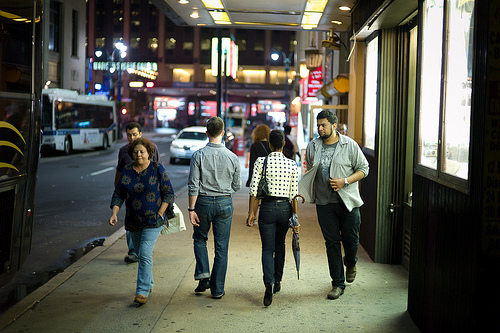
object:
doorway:
[380, 2, 412, 277]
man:
[115, 124, 145, 268]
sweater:
[110, 165, 168, 230]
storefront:
[349, 3, 498, 330]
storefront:
[140, 82, 298, 122]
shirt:
[115, 159, 171, 216]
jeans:
[128, 228, 162, 297]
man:
[304, 108, 374, 297]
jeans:
[187, 193, 234, 305]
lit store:
[418, 0, 473, 187]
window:
[411, 0, 476, 195]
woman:
[244, 123, 309, 311]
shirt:
[246, 148, 303, 201]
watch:
[188, 205, 196, 211]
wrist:
[187, 207, 195, 212]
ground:
[387, 141, 467, 196]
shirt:
[185, 143, 245, 196]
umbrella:
[288, 194, 303, 276]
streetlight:
[109, 36, 126, 150]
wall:
[297, 123, 402, 153]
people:
[303, 108, 376, 302]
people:
[247, 130, 299, 315]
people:
[186, 116, 241, 301]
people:
[107, 136, 175, 309]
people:
[112, 121, 149, 269]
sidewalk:
[0, 139, 410, 330]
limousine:
[167, 125, 211, 165]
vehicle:
[168, 125, 226, 165]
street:
[3, 129, 246, 315]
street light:
[306, 45, 324, 71]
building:
[149, 0, 499, 331]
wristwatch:
[186, 204, 199, 214]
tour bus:
[40, 86, 120, 154]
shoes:
[127, 292, 152, 309]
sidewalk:
[192, 298, 380, 330]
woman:
[103, 130, 179, 305]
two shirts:
[305, 136, 366, 212]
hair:
[125, 136, 153, 163]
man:
[185, 115, 243, 300]